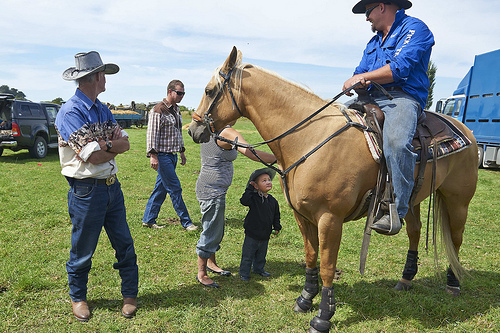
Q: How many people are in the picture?
A: Five.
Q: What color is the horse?
A: Tan.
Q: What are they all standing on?
A: Grass.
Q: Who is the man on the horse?
A: A cowboy.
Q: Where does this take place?
A: On a ranch.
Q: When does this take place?
A: Daytime.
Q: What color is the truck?
A: Blue.